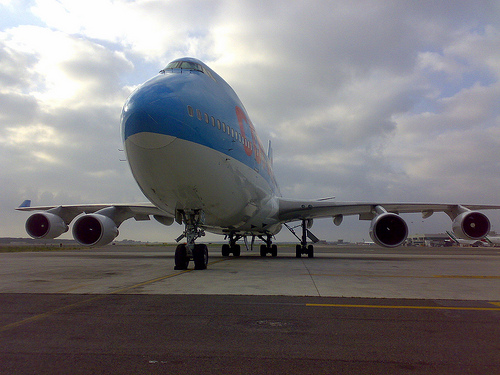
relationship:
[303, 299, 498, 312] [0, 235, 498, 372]
stripe on runway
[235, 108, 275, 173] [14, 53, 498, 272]
writing on aircraft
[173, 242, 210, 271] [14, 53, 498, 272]
wheels are on aircraft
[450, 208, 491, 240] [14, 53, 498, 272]
airplane engine on aircraft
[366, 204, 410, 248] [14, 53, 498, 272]
airplane engine on aircraft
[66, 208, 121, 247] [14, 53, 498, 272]
jet engine on aircraft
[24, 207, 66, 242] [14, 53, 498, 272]
jet engine on aircraft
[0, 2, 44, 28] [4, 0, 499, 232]
patch of sky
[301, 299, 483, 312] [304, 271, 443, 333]
line on runway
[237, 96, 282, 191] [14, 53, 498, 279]
letters are on aircraft